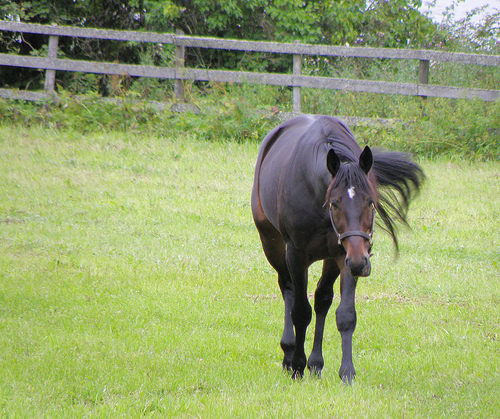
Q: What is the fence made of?
A: Wood.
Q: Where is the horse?
A: In the yard.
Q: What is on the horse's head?
A: A white spot.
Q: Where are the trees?
A: Behind the fence.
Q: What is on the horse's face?
A: A harness.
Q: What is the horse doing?
A: Walking.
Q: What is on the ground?
A: Grass.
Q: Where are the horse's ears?
A: On his head.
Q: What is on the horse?
A: Hair.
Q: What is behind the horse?
A: A fence.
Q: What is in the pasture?
A: A horse.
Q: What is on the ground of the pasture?
A: Grass.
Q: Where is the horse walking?
A: Forward.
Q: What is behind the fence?
A: Trees.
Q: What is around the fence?
A: Weeds.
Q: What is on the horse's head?
A: A halter.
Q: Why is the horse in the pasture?
A: To eat.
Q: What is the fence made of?
A: Wood.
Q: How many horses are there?
A: One.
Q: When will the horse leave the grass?
A: When the owner opens the gate.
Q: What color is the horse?
A: Black and brown.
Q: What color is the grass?
A: Green.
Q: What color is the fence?
A: Gray.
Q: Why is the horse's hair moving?
A: Because it is galloping on the grass.